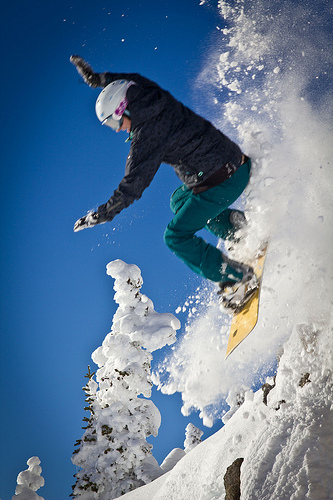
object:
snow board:
[224, 236, 269, 359]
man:
[68, 53, 257, 313]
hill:
[111, 326, 333, 500]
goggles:
[102, 97, 129, 132]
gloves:
[70, 54, 99, 88]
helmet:
[94, 77, 137, 122]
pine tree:
[67, 258, 181, 500]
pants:
[162, 160, 258, 315]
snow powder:
[144, 0, 331, 412]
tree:
[67, 259, 180, 500]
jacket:
[97, 73, 248, 223]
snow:
[243, 383, 331, 499]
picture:
[0, 0, 333, 500]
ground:
[215, 373, 308, 498]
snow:
[90, 258, 180, 369]